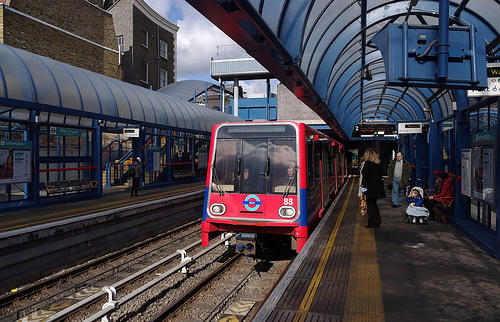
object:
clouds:
[166, 13, 239, 61]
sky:
[165, 49, 220, 83]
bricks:
[323, 261, 350, 280]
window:
[239, 138, 266, 192]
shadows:
[327, 229, 420, 244]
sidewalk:
[318, 154, 475, 319]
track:
[169, 252, 296, 315]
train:
[203, 119, 351, 248]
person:
[127, 159, 142, 197]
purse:
[127, 169, 136, 177]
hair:
[364, 148, 381, 163]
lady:
[360, 148, 386, 228]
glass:
[212, 126, 295, 193]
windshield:
[214, 124, 296, 193]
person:
[425, 171, 453, 224]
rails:
[146, 269, 216, 322]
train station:
[2, 1, 497, 316]